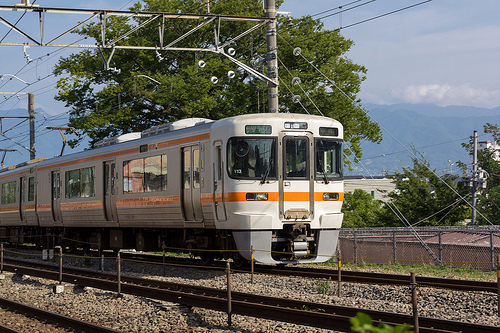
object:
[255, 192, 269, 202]
headlight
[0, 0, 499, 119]
sky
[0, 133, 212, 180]
stripes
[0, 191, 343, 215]
stripes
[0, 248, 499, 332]
gravel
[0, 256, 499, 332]
train tracks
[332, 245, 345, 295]
post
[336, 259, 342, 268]
stripe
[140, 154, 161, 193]
window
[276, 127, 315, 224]
door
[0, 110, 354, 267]
train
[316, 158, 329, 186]
wiper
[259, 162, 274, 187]
wiper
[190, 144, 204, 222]
door